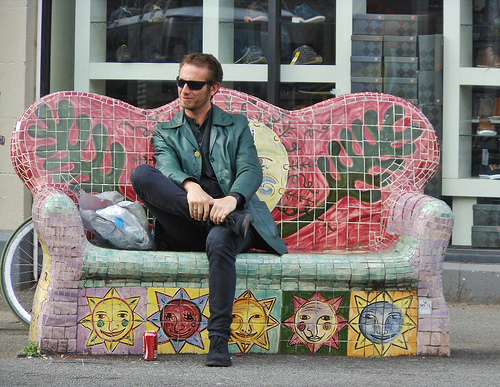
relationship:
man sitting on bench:
[129, 53, 286, 366] [11, 88, 452, 362]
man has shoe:
[129, 53, 286, 366] [208, 337, 232, 366]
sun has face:
[79, 287, 144, 355] [93, 297, 134, 341]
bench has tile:
[11, 88, 452, 362] [345, 102, 364, 124]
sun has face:
[348, 291, 417, 354] [360, 300, 407, 344]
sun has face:
[147, 290, 211, 351] [160, 300, 201, 339]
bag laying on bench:
[73, 188, 158, 251] [11, 88, 452, 362]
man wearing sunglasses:
[129, 53, 286, 366] [175, 77, 210, 89]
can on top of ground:
[142, 331, 159, 362] [2, 289, 498, 385]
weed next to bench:
[24, 340, 40, 355] [11, 88, 452, 362]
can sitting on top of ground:
[142, 331, 159, 362] [2, 289, 498, 385]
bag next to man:
[73, 188, 158, 251] [129, 53, 286, 366]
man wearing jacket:
[129, 53, 286, 366] [151, 104, 289, 254]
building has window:
[1, 2, 500, 288] [105, 2, 337, 109]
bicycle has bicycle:
[1, 216, 44, 329] [0, 217, 44, 328]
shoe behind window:
[208, 337, 232, 366] [105, 2, 337, 109]